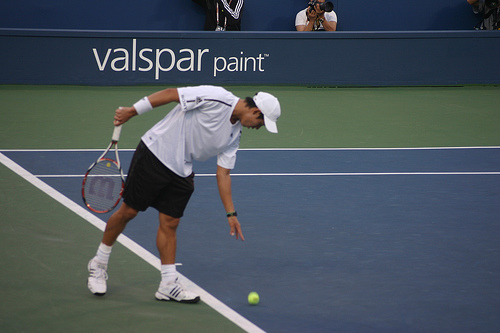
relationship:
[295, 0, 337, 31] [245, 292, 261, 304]
man bouncing ball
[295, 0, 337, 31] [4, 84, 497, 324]
man on court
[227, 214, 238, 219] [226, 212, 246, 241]
watch on hand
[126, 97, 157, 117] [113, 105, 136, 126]
wristband on hand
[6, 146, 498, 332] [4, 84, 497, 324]
lines on court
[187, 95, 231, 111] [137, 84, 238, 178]
stripe on shirt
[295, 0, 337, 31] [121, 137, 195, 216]
man wearing shorts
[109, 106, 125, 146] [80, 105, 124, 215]
grip on racket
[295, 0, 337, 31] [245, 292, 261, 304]
man bending for ball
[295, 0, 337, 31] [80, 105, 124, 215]
man holding racket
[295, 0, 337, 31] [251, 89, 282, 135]
man wearing cap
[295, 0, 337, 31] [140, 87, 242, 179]
man wearing shirt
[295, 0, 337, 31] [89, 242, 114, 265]
man wearing sock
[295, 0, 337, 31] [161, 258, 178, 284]
man wearing sock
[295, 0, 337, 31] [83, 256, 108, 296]
man wearing shoe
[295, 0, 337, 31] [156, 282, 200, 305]
man wearing shoe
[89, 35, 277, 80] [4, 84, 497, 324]
sign in court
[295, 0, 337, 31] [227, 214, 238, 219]
man wearing watch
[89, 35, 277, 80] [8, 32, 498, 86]
sign on wall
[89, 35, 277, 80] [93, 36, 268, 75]
sign reads valspar paint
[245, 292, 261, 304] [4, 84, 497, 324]
ball on court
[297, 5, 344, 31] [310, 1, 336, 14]
man has a camera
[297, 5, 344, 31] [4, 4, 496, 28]
man sitting on side of court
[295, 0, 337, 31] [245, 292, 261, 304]
man picking up ball